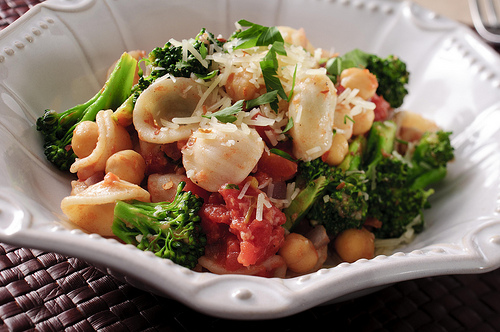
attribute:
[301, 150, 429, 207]
broccoli — cooked , pieces 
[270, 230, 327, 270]
peas — chick, mixture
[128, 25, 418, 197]
cheese —  white , shredded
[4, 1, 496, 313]
bowl — fancy white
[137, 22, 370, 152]
cheese — shredded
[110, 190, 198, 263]
broccoli —  pieces, cut up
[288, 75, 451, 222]
broccoli pasta —  mixture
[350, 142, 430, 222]
broccoli — green 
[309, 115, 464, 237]
broccoli — dark green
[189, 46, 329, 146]
cheese — white 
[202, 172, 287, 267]
tomatoes — red 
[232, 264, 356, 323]
bowl —  white 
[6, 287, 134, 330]
table — dark brown 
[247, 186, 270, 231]
flakes — white 